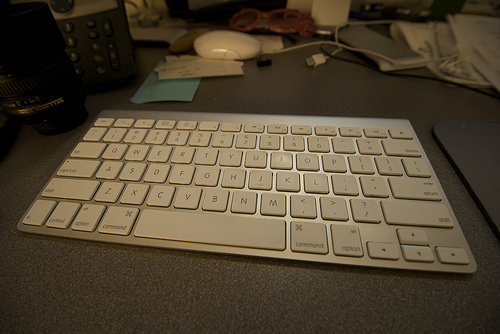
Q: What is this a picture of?
A: A desktop.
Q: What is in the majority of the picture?
A: A keyboard.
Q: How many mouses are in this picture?
A: One.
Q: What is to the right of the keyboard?
A: A mousepad.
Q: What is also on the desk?
A: Papers.